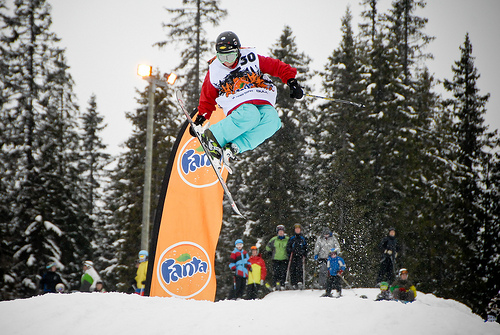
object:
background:
[1, 3, 484, 312]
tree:
[0, 0, 81, 227]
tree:
[0, 133, 99, 299]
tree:
[74, 92, 111, 231]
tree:
[307, 10, 373, 242]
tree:
[252, 27, 324, 254]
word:
[180, 149, 217, 175]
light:
[137, 64, 152, 78]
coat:
[265, 235, 289, 261]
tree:
[427, 30, 500, 322]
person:
[189, 29, 303, 164]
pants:
[203, 105, 282, 151]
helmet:
[216, 31, 241, 52]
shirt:
[198, 46, 298, 120]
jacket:
[132, 262, 149, 287]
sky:
[0, 0, 500, 170]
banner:
[144, 102, 230, 301]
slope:
[1, 287, 500, 335]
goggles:
[217, 52, 239, 63]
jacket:
[327, 256, 347, 276]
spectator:
[321, 250, 346, 298]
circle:
[175, 135, 226, 188]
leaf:
[196, 145, 206, 152]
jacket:
[247, 255, 266, 285]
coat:
[229, 248, 251, 278]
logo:
[157, 241, 212, 299]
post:
[139, 59, 157, 253]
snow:
[308, 221, 368, 286]